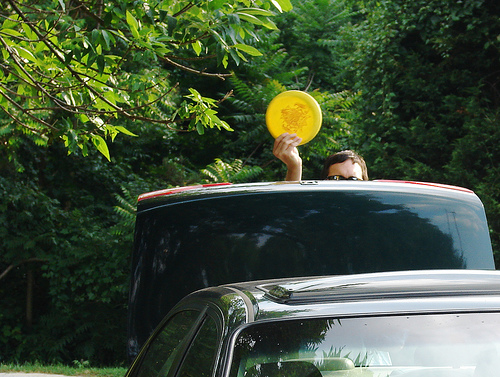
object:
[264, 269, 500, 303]
sunroof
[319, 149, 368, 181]
hair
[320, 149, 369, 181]
head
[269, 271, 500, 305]
dark slat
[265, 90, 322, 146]
frisbee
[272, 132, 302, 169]
hand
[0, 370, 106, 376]
road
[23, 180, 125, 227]
leaves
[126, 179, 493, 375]
car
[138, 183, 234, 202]
tail light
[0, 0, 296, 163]
green tree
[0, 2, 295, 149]
leaves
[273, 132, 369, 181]
catcher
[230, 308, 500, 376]
windshield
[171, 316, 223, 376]
window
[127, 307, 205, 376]
window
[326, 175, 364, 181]
glasses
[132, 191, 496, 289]
reflection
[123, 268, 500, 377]
car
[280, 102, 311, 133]
design